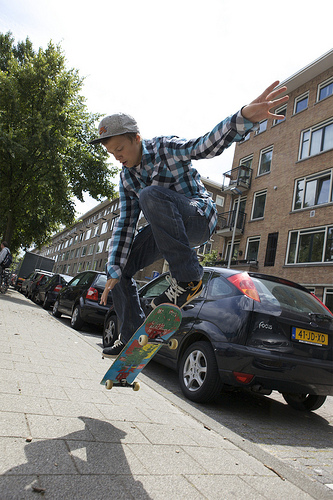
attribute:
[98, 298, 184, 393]
skateboard — colorful, blue, green, yellow, red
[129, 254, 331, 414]
car — parked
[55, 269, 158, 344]
car — parked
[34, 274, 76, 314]
car — parked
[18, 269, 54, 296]
car — parked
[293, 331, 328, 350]
license — yellow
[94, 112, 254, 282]
shirt — plaid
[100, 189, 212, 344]
jeans — denim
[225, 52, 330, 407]
building — brick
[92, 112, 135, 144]
hat — grey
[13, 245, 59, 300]
truck — parked